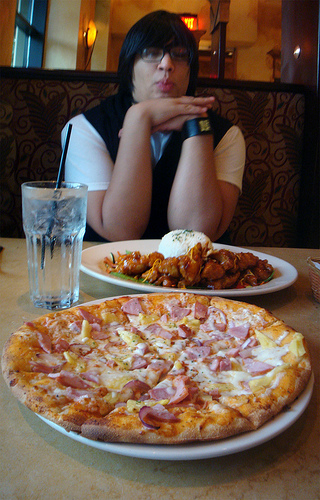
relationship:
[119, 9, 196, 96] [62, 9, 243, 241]
head of a person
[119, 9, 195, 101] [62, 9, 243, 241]
head of a person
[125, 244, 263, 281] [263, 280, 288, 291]
food on plate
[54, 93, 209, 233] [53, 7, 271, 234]
arm of a person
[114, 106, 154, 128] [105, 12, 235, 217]
wrist of a person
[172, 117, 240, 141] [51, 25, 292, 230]
wrist of a person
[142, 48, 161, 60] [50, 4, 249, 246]
eye of a person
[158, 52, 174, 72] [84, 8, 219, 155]
nose of a person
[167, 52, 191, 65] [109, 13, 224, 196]
eye of a person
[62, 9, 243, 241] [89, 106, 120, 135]
person wearing a vest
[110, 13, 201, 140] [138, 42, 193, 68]
person wearing glasses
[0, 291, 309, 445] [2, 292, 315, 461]
pizza on a plate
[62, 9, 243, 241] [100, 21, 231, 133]
person has head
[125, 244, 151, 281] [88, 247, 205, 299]
food on dish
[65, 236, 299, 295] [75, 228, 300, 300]
plate a plate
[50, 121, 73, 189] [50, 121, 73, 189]
straw a straw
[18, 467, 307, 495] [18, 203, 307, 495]
table a table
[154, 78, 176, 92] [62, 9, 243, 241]
mouth of a person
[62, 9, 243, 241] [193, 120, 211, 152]
person wearing a wrist band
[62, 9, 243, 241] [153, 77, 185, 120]
person puckering up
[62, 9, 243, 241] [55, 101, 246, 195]
person wearing a white shirt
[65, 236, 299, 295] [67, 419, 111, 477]
plate made of ceramic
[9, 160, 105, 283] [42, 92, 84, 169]
glass with a straw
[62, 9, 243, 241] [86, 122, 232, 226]
person posing for a picture